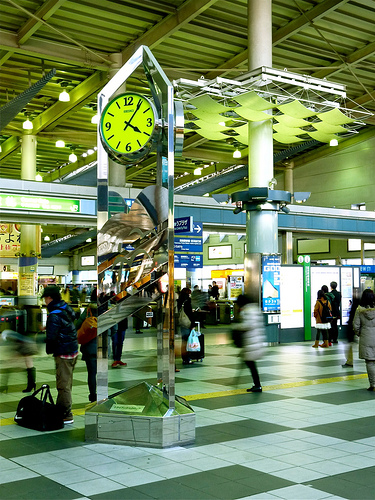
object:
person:
[39, 286, 79, 424]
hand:
[123, 120, 141, 134]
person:
[230, 291, 267, 398]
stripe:
[180, 373, 369, 402]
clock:
[99, 90, 159, 164]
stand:
[95, 149, 175, 410]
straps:
[31, 383, 54, 405]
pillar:
[246, 0, 278, 253]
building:
[0, 0, 372, 497]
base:
[84, 382, 196, 450]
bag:
[178, 300, 191, 329]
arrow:
[97, 44, 175, 179]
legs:
[55, 355, 75, 418]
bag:
[14, 385, 71, 433]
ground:
[69, 446, 308, 469]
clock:
[97, 90, 167, 161]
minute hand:
[123, 100, 143, 132]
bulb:
[58, 88, 71, 103]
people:
[312, 290, 332, 348]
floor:
[0, 302, 373, 498]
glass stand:
[84, 40, 195, 447]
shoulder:
[184, 297, 192, 306]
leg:
[244, 359, 263, 394]